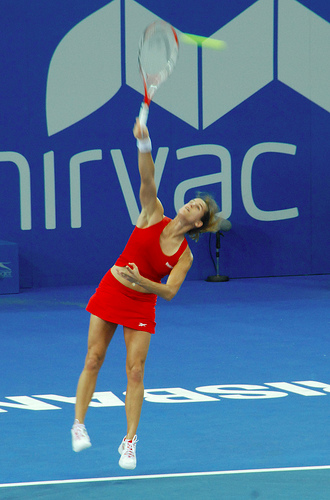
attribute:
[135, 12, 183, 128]
racquet — red, white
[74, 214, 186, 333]
outfit — red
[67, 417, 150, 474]
shoes — white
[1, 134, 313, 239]
words — white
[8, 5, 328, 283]
wall — blue, white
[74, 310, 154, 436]
legs — muscular, tan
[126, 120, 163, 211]
arm — muscular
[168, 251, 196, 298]
arm — muscular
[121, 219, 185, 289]
shirt — red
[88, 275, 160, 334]
skirt — red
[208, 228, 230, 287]
stand — black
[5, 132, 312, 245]
letters — white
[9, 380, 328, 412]
letters — white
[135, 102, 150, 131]
handle — white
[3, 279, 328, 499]
court — blue